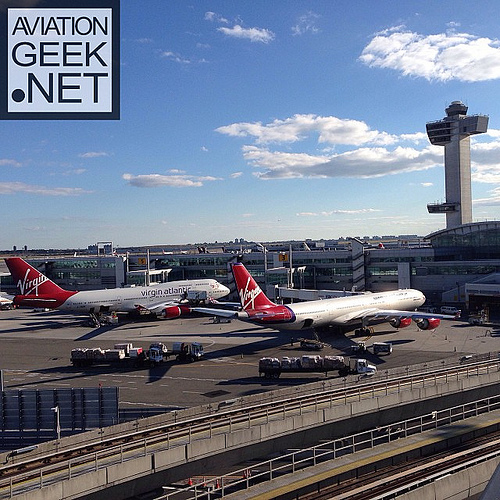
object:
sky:
[0, 0, 493, 248]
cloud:
[216, 105, 435, 186]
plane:
[3, 247, 234, 337]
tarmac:
[1, 326, 460, 366]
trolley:
[300, 338, 324, 349]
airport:
[188, 261, 462, 351]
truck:
[70, 343, 163, 368]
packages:
[71, 347, 126, 360]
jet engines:
[388, 316, 440, 330]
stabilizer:
[187, 302, 330, 323]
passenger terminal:
[154, 245, 421, 285]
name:
[140, 287, 191, 297]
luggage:
[258, 355, 345, 369]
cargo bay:
[258, 355, 378, 380]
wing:
[369, 308, 456, 321]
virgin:
[17, 268, 50, 297]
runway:
[9, 301, 320, 397]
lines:
[107, 373, 235, 382]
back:
[8, 227, 500, 260]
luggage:
[373, 342, 393, 356]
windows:
[250, 260, 397, 290]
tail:
[185, 261, 289, 325]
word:
[236, 276, 264, 310]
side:
[260, 294, 458, 337]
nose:
[402, 288, 426, 310]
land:
[2, 289, 476, 407]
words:
[8, 12, 108, 107]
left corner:
[0, 0, 121, 122]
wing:
[187, 306, 246, 320]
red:
[165, 306, 179, 318]